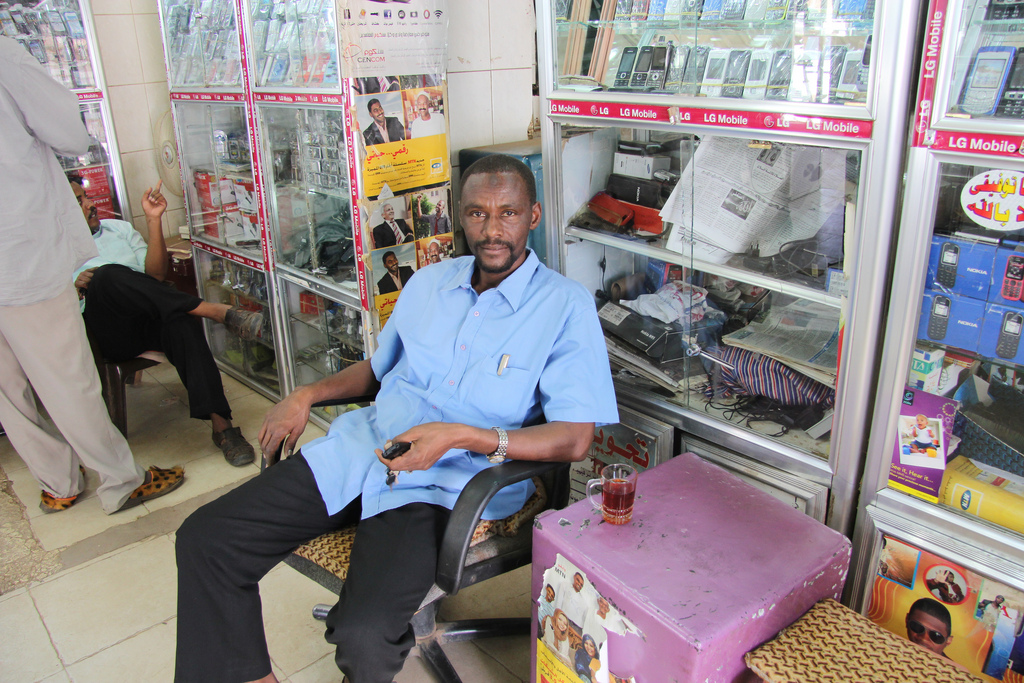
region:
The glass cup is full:
[584, 464, 639, 534]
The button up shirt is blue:
[299, 250, 620, 519]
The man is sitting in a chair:
[171, 151, 618, 680]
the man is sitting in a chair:
[66, 170, 264, 469]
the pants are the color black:
[176, 452, 445, 680]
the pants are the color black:
[76, 262, 232, 422]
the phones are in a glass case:
[555, 3, 875, 108]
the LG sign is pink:
[547, 98, 873, 137]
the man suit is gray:
[0, 32, 188, 510]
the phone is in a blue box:
[928, 233, 996, 306]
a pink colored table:
[527, 451, 856, 679]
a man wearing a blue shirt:
[176, 149, 619, 680]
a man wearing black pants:
[174, 146, 620, 679]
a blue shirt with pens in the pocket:
[299, 241, 625, 517]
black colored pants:
[79, 263, 228, 413]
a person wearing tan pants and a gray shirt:
[0, 26, 184, 511]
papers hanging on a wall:
[332, 3, 551, 333]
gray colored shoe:
[202, 418, 256, 464]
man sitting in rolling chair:
[190, 135, 614, 667]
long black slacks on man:
[150, 445, 435, 679]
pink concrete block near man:
[541, 443, 875, 678]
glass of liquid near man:
[588, 456, 653, 536]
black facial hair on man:
[454, 233, 518, 276]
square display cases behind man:
[168, 41, 437, 402]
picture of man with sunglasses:
[895, 598, 950, 656]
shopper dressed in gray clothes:
[0, 31, 147, 481]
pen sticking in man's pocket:
[484, 351, 523, 387]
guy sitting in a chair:
[170, 152, 619, 680]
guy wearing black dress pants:
[170, 151, 614, 679]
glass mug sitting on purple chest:
[587, 461, 641, 523]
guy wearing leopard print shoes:
[0, 42, 194, 508]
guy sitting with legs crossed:
[71, 168, 253, 478]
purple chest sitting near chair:
[533, 454, 854, 674]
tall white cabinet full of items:
[532, 0, 910, 602]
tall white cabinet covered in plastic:
[137, 0, 458, 454]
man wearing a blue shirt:
[299, 239, 629, 509]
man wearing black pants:
[145, 423, 463, 676]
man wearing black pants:
[75, 252, 241, 461]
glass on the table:
[569, 449, 640, 519]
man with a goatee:
[457, 230, 518, 273]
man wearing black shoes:
[195, 298, 288, 333]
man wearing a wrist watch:
[492, 417, 509, 466]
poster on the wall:
[345, 123, 456, 194]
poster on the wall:
[340, 0, 455, 197]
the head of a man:
[422, 134, 560, 291]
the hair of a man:
[460, 144, 534, 196]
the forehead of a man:
[460, 173, 530, 205]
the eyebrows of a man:
[460, 191, 530, 218]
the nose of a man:
[462, 213, 526, 249]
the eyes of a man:
[457, 204, 522, 225]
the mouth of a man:
[469, 230, 517, 262]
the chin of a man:
[466, 252, 518, 278]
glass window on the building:
[245, 0, 340, 89]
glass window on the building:
[159, 96, 259, 265]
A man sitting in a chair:
[157, 138, 626, 677]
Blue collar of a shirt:
[435, 232, 543, 316]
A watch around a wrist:
[468, 411, 517, 481]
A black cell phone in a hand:
[364, 408, 466, 478]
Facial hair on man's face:
[452, 220, 528, 279]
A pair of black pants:
[70, 247, 257, 431]